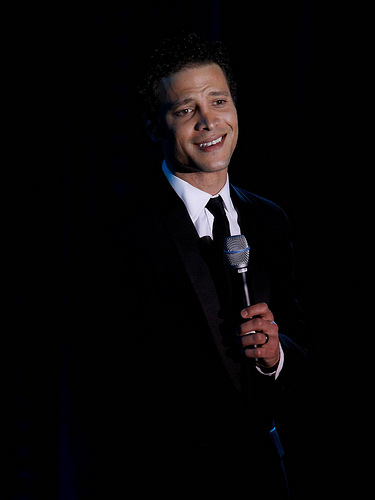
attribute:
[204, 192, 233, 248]
tie — black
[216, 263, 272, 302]
microphone — silver, black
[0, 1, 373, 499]
background — black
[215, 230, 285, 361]
mic — black, silver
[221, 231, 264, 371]
microphone — silver, black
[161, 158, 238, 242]
shirt — white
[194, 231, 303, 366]
microphone — Black , silver 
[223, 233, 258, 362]
microphone — small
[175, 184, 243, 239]
shirt — white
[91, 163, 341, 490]
coat — black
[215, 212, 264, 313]
microphone — black, silver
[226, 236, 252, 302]
microphone — black, silver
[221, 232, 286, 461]
microphone — Black , silver 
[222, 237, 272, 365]
microphone — black, silver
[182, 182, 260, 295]
tie — long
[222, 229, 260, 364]
microphone — silver, black